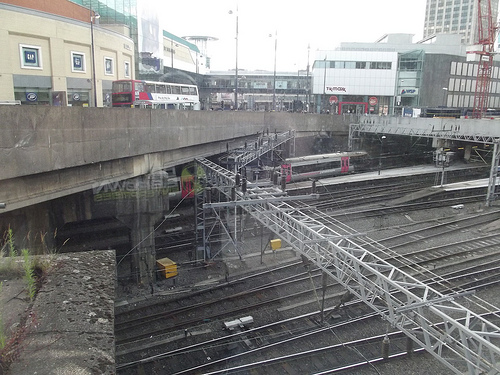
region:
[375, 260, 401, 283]
metal truss on bridge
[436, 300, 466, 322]
metal truss on bridge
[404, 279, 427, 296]
metal truss on bridge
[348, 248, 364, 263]
metal truss on bridge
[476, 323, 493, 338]
metal truss on bridge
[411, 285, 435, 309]
metal truss on bridge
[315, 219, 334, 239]
metal truss on bridge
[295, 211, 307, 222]
metal truss on bridge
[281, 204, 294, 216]
metal truss on bridge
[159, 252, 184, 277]
yellow box container on cement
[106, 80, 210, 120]
red blue and white bus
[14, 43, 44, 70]
blue and white gap sign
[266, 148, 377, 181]
black red and black train on tracks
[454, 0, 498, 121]
red crane machine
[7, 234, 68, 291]
small weeds growing in cement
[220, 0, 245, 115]
large street light lamps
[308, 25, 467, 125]
multi layered commercial building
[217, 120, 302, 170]
railway traffic signal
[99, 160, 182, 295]
concrete support slab base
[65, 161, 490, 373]
A large train yard with many tracks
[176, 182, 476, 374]
a lot of train tracks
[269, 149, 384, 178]
A train on a track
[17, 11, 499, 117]
Buildings above the train tracks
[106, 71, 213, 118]
A bus on the street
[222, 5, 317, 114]
Light poles in a row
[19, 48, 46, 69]
A sign that says GAP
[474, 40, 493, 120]
A red tower above the train tracks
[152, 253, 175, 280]
Yellow box near the train tracks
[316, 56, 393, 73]
Windows on the building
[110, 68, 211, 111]
White, Red and Blue bus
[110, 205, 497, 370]
Railroad tracks which join up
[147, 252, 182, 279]
Yellow box on ground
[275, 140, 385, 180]
Red and white train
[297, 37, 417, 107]
White building with lots of windows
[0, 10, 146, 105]
Curved building with GAP store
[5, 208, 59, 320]
Weeds growing out of cement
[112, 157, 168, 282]
Cement support for bridge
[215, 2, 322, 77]
Street lights along the road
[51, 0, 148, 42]
Taller building with window facade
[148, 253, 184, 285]
yellow crate on the ground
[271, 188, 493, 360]
metal structure over tracts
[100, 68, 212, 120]
a double decker bus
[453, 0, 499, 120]
a red construction crane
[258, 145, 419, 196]
a train on its tracks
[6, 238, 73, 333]
weeds growing from cracks in cement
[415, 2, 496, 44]
a high rise building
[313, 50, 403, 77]
windows on a white building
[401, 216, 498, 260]
several sets of train tracks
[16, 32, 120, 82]
blue GAP signs